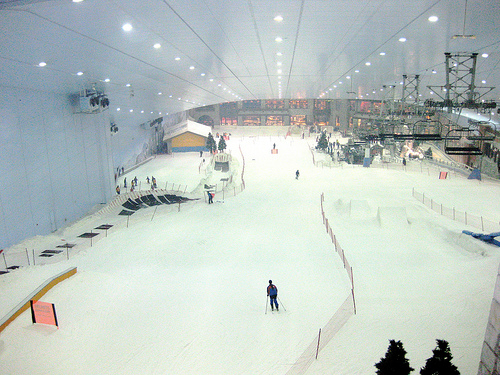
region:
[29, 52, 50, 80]
light in dome stadium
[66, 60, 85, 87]
light in dome stadium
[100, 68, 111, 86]
light in dome stadium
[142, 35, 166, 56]
light in dome stadium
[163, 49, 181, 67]
light in dome stadium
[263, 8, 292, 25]
light in dome stadium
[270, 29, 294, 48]
light in dome stadium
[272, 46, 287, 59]
light in dome stadium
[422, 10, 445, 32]
light in dome stadium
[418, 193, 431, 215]
part of red fence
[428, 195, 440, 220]
part of red fence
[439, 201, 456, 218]
part of red fence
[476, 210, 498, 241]
part of red fence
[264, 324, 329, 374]
part of red fence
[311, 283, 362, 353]
part of red fence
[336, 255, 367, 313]
part of red fence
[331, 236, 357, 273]
part of red fence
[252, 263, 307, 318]
a skiier is alone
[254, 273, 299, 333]
skier with multi colored jacket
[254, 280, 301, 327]
skiier has 2 poles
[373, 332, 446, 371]
2 green trees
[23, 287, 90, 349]
a see-through orange sign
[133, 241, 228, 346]
clear clean white snow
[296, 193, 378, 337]
a fence with poles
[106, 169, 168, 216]
a group of people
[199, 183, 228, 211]
a kid is alone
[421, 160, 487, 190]
a orange and blue object